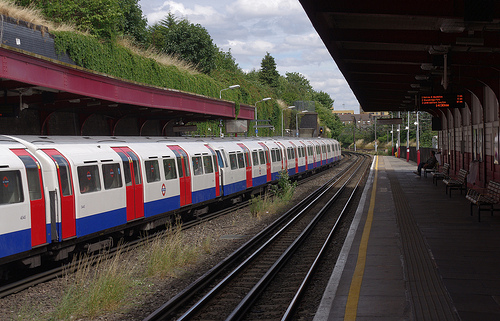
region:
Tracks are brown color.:
[249, 189, 348, 257]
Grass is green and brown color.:
[81, 238, 172, 307]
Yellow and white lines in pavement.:
[339, 228, 389, 293]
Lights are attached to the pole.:
[221, 76, 370, 151]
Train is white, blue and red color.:
[4, 137, 287, 239]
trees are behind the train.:
[88, 16, 310, 93]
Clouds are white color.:
[243, 15, 311, 68]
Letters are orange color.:
[404, 85, 470, 115]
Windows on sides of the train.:
[7, 135, 343, 208]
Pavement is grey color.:
[393, 213, 460, 298]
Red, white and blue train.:
[2, 115, 346, 266]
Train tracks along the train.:
[151, 151, 371, 318]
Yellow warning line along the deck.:
[346, 151, 381, 319]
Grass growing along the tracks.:
[28, 175, 297, 320]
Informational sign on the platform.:
[416, 88, 467, 113]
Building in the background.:
[328, 96, 420, 154]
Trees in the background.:
[29, 5, 341, 136]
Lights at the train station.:
[208, 83, 425, 165]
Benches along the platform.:
[422, 153, 499, 214]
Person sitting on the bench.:
[413, 148, 444, 183]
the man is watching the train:
[413, 145, 441, 180]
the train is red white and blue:
[58, 145, 178, 203]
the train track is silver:
[293, 233, 322, 293]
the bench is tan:
[458, 186, 497, 205]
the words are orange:
[415, 91, 449, 108]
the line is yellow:
[353, 244, 369, 280]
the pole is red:
[412, 148, 424, 165]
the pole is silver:
[411, 129, 423, 146]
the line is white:
[333, 242, 346, 284]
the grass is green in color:
[146, 241, 205, 268]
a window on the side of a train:
[76, 163, 102, 193]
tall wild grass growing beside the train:
[268, 166, 296, 202]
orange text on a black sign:
[417, 90, 468, 109]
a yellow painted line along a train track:
[342, 153, 379, 319]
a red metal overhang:
[0, 43, 255, 121]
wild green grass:
[54, 239, 131, 315]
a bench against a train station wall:
[465, 175, 497, 215]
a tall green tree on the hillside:
[260, 50, 277, 87]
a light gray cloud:
[229, 0, 297, 44]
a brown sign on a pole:
[376, 118, 401, 126]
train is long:
[0, 139, 329, 211]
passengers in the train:
[75, 162, 124, 190]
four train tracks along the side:
[234, 202, 339, 307]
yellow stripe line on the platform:
[346, 160, 373, 320]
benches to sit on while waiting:
[430, 165, 489, 242]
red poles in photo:
[395, 140, 421, 168]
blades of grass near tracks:
[67, 240, 205, 280]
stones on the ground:
[11, 277, 71, 318]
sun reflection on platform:
[375, 153, 414, 173]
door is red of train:
[116, 149, 147, 223]